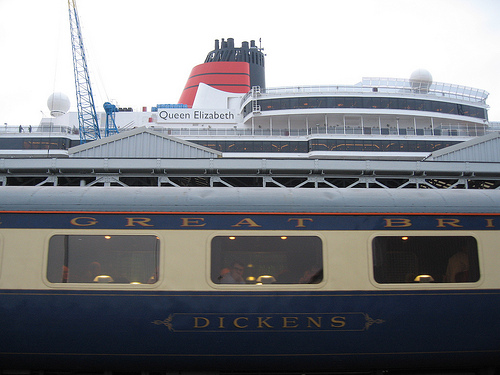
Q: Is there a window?
A: Yes, there are windows.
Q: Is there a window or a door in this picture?
A: Yes, there are windows.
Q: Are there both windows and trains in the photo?
A: Yes, there are both windows and a train.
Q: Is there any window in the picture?
A: Yes, there are windows.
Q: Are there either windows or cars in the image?
A: Yes, there are windows.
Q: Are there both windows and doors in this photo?
A: No, there are windows but no doors.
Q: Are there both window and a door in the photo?
A: No, there are windows but no doors.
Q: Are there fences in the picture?
A: No, there are no fences.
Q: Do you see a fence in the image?
A: No, there are no fences.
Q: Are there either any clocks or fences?
A: No, there are no fences or clocks.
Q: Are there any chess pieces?
A: No, there are no chess pieces.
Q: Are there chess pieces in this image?
A: No, there are no chess pieces.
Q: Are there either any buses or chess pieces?
A: No, there are no chess pieces or buses.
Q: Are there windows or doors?
A: Yes, there are windows.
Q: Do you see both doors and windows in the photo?
A: No, there are windows but no doors.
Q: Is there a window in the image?
A: Yes, there is a window.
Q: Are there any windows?
A: Yes, there is a window.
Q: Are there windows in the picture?
A: Yes, there is a window.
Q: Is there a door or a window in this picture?
A: Yes, there is a window.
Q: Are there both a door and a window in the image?
A: No, there is a window but no doors.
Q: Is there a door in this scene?
A: No, there are no doors.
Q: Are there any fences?
A: No, there are no fences.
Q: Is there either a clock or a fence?
A: No, there are no fences or clocks.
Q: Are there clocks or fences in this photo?
A: No, there are no fences or clocks.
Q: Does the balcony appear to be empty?
A: Yes, the balcony is empty.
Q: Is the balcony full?
A: No, the balcony is empty.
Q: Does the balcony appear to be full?
A: No, the balcony is empty.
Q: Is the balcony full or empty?
A: The balcony is empty.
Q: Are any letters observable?
A: Yes, there are letters.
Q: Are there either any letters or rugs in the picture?
A: Yes, there are letters.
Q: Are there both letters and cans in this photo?
A: No, there are letters but no cans.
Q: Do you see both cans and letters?
A: No, there are letters but no cans.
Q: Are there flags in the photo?
A: No, there are no flags.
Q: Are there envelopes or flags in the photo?
A: No, there are no flags or envelopes.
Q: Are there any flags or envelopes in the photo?
A: No, there are no flags or envelopes.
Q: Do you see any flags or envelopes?
A: No, there are no flags or envelopes.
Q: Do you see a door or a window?
A: Yes, there are windows.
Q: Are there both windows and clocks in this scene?
A: No, there are windows but no clocks.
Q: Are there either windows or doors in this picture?
A: Yes, there are windows.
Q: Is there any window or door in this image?
A: Yes, there are windows.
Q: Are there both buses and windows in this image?
A: No, there are windows but no buses.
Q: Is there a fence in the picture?
A: No, there are no fences.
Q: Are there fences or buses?
A: No, there are no fences or buses.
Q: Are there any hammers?
A: No, there are no hammers.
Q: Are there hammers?
A: No, there are no hammers.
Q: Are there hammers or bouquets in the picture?
A: No, there are no hammers or bouquets.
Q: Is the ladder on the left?
A: Yes, the ladder is on the left of the image.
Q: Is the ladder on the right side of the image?
A: No, the ladder is on the left of the image.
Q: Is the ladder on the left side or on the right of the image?
A: The ladder is on the left of the image.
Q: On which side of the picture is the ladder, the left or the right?
A: The ladder is on the left of the image.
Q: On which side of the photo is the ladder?
A: The ladder is on the left of the image.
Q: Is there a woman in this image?
A: No, there are no women.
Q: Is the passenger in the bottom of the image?
A: Yes, the passenger is in the bottom of the image.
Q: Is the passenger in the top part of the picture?
A: No, the passenger is in the bottom of the image.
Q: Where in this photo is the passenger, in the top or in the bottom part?
A: The passenger is in the bottom of the image.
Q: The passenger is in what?
A: The passenger is in the window.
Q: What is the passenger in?
A: The passenger is in the window.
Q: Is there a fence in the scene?
A: No, there are no fences.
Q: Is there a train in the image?
A: Yes, there is a train.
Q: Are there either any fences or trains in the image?
A: Yes, there is a train.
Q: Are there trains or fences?
A: Yes, there is a train.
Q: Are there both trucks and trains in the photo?
A: No, there is a train but no trucks.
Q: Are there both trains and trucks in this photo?
A: No, there is a train but no trucks.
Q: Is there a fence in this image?
A: No, there are no fences.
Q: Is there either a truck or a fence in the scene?
A: No, there are no fences or trucks.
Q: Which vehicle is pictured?
A: The vehicle is a train.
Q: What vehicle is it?
A: The vehicle is a train.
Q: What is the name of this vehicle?
A: This is a train.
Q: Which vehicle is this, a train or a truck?
A: This is a train.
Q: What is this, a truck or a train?
A: This is a train.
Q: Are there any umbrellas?
A: No, there are no umbrellas.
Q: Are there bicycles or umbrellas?
A: No, there are no umbrellas or bicycles.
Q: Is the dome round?
A: Yes, the dome is round.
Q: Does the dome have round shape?
A: Yes, the dome is round.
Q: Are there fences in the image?
A: No, there are no fences.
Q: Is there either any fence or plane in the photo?
A: No, there are no fences or airplanes.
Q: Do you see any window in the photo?
A: Yes, there is a window.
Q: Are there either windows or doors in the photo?
A: Yes, there is a window.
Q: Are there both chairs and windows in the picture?
A: No, there is a window but no chairs.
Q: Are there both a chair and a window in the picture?
A: No, there is a window but no chairs.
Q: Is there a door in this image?
A: No, there are no doors.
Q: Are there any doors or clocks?
A: No, there are no doors or clocks.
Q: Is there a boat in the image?
A: Yes, there is a boat.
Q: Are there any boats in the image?
A: Yes, there is a boat.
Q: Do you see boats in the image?
A: Yes, there is a boat.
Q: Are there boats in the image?
A: Yes, there is a boat.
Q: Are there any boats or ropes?
A: Yes, there is a boat.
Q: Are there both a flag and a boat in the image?
A: No, there is a boat but no flags.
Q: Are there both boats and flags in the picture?
A: No, there is a boat but no flags.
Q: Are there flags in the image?
A: No, there are no flags.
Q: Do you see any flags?
A: No, there are no flags.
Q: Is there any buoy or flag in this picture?
A: No, there are no flags or buoys.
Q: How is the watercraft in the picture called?
A: The watercraft is a boat.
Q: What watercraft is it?
A: The watercraft is a boat.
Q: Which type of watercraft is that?
A: This is a boat.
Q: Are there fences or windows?
A: Yes, there are windows.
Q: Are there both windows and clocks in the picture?
A: No, there are windows but no clocks.